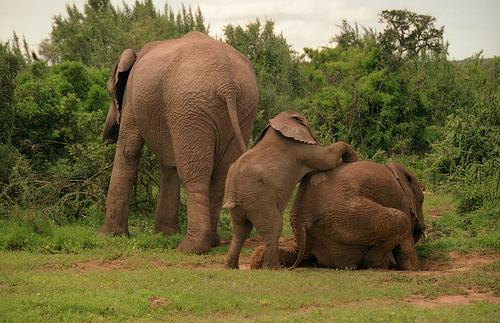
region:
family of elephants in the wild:
[80, 58, 456, 295]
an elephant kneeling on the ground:
[288, 160, 420, 285]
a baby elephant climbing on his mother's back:
[216, 112, 310, 270]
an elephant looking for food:
[100, 43, 235, 248]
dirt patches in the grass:
[408, 276, 478, 313]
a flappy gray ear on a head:
[271, 111, 308, 142]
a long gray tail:
[221, 94, 253, 149]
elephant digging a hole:
[306, 159, 423, 261]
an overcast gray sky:
[289, 4, 489, 19]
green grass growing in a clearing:
[59, 282, 96, 317]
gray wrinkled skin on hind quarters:
[176, 96, 198, 141]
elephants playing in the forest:
[40, 16, 480, 272]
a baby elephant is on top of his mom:
[220, 105, 437, 285]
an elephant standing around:
[92, 25, 259, 265]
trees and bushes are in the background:
[5, 2, 496, 208]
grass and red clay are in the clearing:
[2, 215, 492, 315]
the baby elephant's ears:
[247, 107, 317, 142]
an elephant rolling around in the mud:
[247, 155, 432, 280]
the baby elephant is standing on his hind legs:
[220, 108, 356, 264]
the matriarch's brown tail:
[212, 76, 252, 161]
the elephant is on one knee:
[245, 161, 328, 273]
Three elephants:
[101, 37, 426, 319]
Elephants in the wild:
[77, 23, 426, 296]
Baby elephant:
[216, 129, 348, 256]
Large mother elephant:
[81, 11, 304, 241]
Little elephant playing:
[192, 90, 459, 280]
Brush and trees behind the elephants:
[28, 92, 228, 232]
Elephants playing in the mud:
[195, 115, 456, 277]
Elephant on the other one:
[200, 32, 405, 317]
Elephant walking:
[115, 5, 236, 250]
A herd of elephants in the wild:
[87, 18, 419, 308]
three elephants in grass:
[48, 35, 498, 295]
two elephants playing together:
[173, 56, 465, 301]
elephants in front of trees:
[28, 0, 498, 290]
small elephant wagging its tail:
[200, 67, 350, 276]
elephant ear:
[266, 104, 320, 156]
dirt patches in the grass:
[27, 208, 499, 313]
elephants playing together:
[51, 3, 466, 294]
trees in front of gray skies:
[321, 5, 498, 105]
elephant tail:
[196, 66, 263, 168]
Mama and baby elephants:
[13, 8, 468, 307]